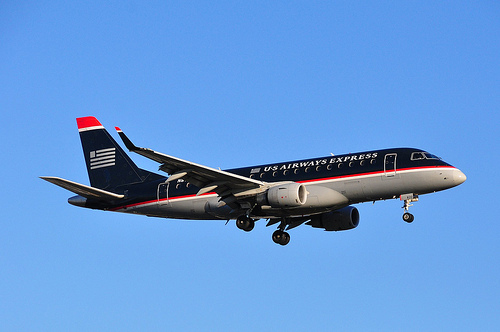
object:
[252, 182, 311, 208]
propeller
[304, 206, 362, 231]
propeller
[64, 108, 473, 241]
plane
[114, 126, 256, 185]
wing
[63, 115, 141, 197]
tail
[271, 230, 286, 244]
tires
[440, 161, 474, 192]
nose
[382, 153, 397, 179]
door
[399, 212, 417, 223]
wheel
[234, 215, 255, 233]
hind wheel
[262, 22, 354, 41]
sky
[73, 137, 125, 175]
flag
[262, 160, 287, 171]
white words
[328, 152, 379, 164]
express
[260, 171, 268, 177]
windows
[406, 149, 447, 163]
windows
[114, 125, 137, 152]
wing tip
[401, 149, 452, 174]
cockpit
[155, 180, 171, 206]
back door